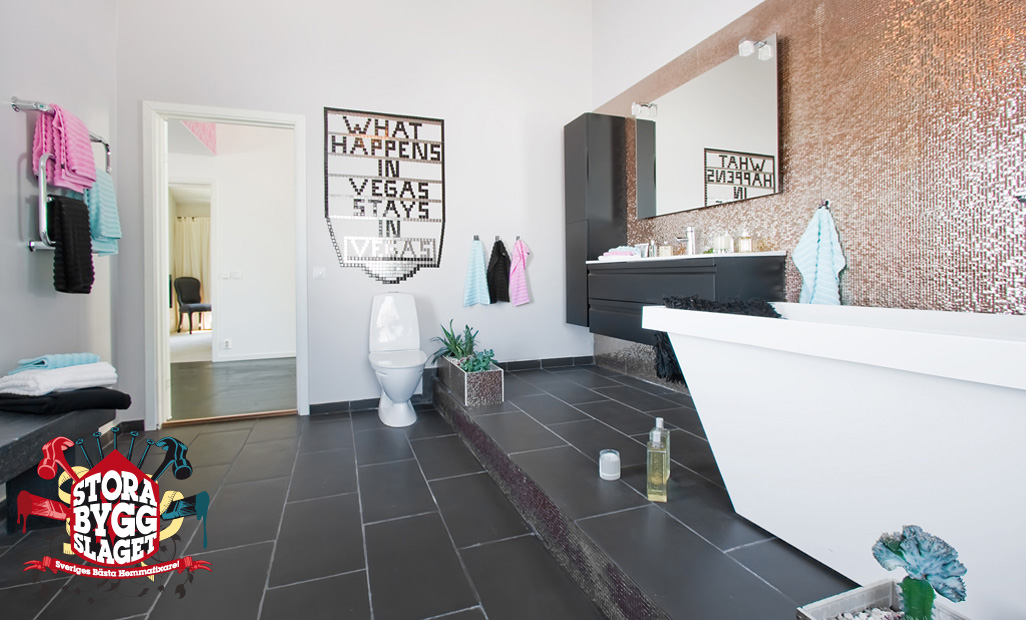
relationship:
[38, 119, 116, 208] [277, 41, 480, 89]
towel hanging on a wall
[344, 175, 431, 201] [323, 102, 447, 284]
vegas on sign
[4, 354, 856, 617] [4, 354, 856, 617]
lines on floor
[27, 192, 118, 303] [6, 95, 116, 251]
towel hanging on rack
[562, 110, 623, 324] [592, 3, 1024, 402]
cabinet mounted on wall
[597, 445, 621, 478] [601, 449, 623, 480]
candle in glass holder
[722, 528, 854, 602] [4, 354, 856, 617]
tile on floor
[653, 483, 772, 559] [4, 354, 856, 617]
tile on floor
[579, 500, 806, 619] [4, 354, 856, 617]
tile on floor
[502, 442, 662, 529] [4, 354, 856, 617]
tile on floor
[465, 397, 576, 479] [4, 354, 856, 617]
tile on floor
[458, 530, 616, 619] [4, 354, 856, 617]
tile on floor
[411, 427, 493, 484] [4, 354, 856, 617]
tile on floor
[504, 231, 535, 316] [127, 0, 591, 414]
towel hanging on wall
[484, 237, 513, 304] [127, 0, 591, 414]
towel hanging on wall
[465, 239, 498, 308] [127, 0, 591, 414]
towel hanging on wall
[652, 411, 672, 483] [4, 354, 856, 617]
bottle on floor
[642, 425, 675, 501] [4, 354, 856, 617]
bottle on floor